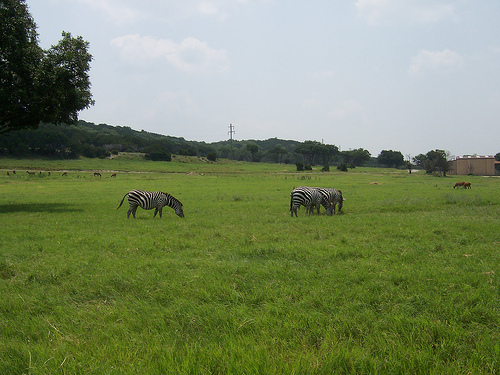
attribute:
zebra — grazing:
[117, 187, 194, 227]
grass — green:
[55, 245, 452, 357]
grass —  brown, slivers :
[19, 305, 127, 371]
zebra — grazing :
[287, 183, 325, 212]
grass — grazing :
[55, 280, 411, 357]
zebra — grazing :
[284, 184, 321, 220]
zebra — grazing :
[323, 189, 343, 215]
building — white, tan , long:
[449, 161, 485, 179]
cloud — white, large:
[137, 51, 273, 96]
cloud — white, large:
[358, 30, 476, 128]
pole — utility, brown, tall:
[222, 114, 248, 177]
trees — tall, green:
[11, 5, 91, 136]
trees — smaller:
[10, 131, 111, 158]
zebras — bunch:
[118, 180, 346, 222]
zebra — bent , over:
[124, 185, 187, 226]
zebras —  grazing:
[287, 185, 350, 219]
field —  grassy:
[13, 168, 482, 360]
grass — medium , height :
[78, 232, 467, 352]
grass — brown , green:
[89, 275, 214, 370]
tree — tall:
[10, 1, 89, 121]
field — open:
[24, 173, 473, 351]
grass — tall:
[130, 276, 475, 364]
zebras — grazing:
[117, 191, 366, 218]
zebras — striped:
[118, 184, 346, 217]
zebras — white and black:
[115, 184, 348, 220]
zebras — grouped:
[115, 181, 351, 219]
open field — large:
[6, 159, 498, 371]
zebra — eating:
[113, 183, 191, 226]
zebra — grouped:
[282, 181, 351, 222]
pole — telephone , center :
[211, 117, 252, 139]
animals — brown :
[199, 126, 476, 260]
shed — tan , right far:
[444, 145, 483, 192]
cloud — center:
[281, 14, 438, 93]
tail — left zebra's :
[113, 178, 136, 203]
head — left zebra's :
[108, 186, 203, 231]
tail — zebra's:
[101, 183, 140, 211]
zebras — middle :
[107, 176, 352, 235]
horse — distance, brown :
[287, 147, 467, 200]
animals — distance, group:
[269, 149, 367, 235]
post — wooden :
[224, 120, 237, 140]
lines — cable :
[180, 112, 356, 144]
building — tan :
[443, 145, 482, 189]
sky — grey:
[98, 18, 471, 142]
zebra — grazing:
[275, 180, 358, 223]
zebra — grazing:
[120, 186, 205, 226]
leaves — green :
[39, 77, 60, 92]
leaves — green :
[15, 64, 35, 74]